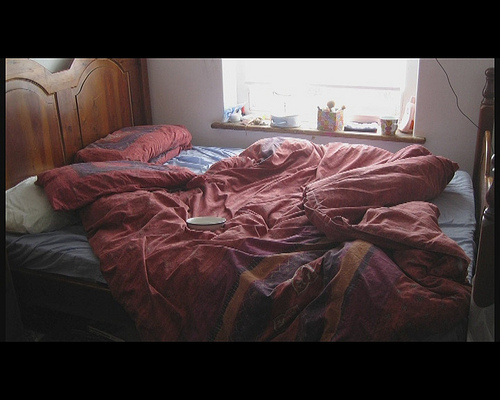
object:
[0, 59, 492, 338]
bed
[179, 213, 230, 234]
bowl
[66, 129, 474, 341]
duvet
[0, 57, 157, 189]
headboard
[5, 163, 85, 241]
pillow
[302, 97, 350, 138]
stuff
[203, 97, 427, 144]
windowsill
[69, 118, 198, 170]
case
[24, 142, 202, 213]
case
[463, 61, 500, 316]
frame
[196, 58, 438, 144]
window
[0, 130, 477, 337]
mattress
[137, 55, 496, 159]
side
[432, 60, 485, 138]
wire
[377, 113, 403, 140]
mug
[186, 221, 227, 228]
rim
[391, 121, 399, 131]
handle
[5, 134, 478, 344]
blankets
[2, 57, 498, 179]
wall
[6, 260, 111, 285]
line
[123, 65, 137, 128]
stripe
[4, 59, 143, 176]
pattern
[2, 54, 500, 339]
bedroom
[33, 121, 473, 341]
bedspread